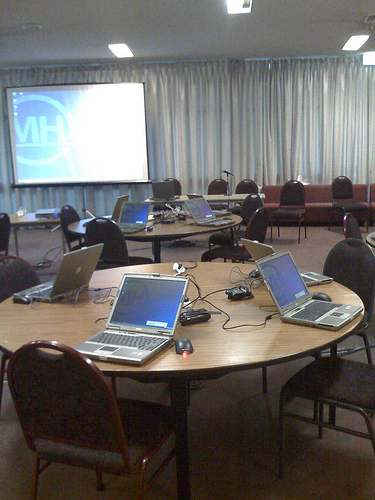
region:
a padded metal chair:
[2, 335, 175, 495]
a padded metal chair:
[270, 353, 373, 475]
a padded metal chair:
[321, 238, 370, 357]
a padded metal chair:
[85, 216, 148, 271]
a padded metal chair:
[0, 252, 36, 300]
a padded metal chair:
[59, 203, 83, 251]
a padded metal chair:
[265, 176, 306, 241]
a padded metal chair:
[329, 174, 361, 227]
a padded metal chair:
[340, 214, 371, 244]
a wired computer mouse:
[175, 334, 192, 357]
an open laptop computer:
[70, 268, 186, 368]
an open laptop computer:
[248, 250, 361, 333]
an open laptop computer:
[239, 236, 331, 293]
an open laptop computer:
[10, 239, 103, 302]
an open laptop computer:
[179, 197, 228, 226]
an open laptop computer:
[109, 200, 150, 232]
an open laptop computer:
[98, 192, 129, 220]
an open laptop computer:
[151, 179, 175, 198]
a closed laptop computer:
[37, 207, 62, 215]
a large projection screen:
[4, 83, 151, 185]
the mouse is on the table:
[172, 331, 195, 359]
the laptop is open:
[75, 262, 194, 362]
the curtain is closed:
[161, 65, 363, 158]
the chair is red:
[9, 332, 157, 494]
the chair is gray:
[278, 356, 368, 456]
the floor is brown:
[213, 441, 251, 498]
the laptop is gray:
[255, 253, 370, 331]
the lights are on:
[91, 27, 370, 63]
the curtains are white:
[150, 58, 366, 171]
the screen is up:
[6, 81, 162, 189]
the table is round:
[0, 254, 374, 498]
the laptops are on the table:
[10, 242, 358, 364]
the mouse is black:
[172, 334, 193, 368]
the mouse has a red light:
[174, 344, 197, 361]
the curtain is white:
[0, 57, 372, 240]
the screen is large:
[1, 75, 149, 192]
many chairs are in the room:
[0, 171, 372, 496]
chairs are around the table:
[0, 234, 374, 489]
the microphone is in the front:
[211, 165, 249, 253]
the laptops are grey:
[12, 243, 358, 364]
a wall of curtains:
[13, 54, 362, 215]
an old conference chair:
[2, 335, 188, 487]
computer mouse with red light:
[173, 334, 197, 358]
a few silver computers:
[11, 238, 361, 374]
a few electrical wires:
[177, 260, 232, 328]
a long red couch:
[247, 178, 373, 219]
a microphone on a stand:
[218, 166, 235, 203]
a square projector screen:
[0, 71, 179, 201]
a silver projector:
[28, 196, 75, 224]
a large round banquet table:
[9, 246, 356, 436]